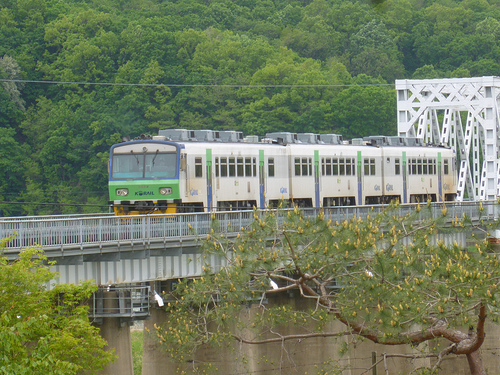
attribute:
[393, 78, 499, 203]
pillars — metal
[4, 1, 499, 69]
trees — thick, green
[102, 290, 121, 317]
pillars — brown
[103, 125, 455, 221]
train — passenger, white, green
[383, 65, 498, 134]
bridge — white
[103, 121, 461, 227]
train — in the picture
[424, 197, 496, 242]
bridge — white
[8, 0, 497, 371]
picture — in the picture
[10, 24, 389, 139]
trees — green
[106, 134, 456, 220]
train — pasenger, in the picture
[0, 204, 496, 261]
bridge — long, metal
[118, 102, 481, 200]
train — passenger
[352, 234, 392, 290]
flowers — in the picture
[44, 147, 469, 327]
bridge — in the picture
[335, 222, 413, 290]
fruits — in the picture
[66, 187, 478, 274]
tracks — in the picture